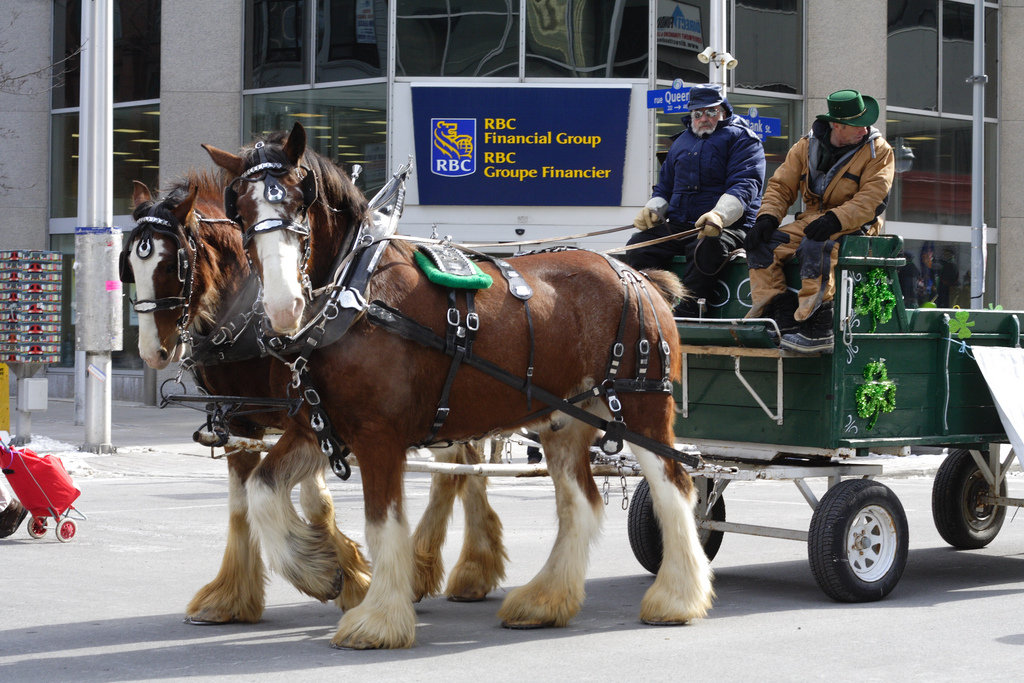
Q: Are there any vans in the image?
A: No, there are no vans.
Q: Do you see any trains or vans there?
A: No, there are no vans or trains.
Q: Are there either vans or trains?
A: No, there are no vans or trains.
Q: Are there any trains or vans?
A: No, there are no vans or trains.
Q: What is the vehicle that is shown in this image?
A: The vehicle is a wagon.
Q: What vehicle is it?
A: The vehicle is a wagon.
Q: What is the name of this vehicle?
A: This is a wagon.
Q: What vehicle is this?
A: This is a wagon.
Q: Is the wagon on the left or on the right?
A: The wagon is on the right of the image.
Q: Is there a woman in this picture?
A: No, there are no women.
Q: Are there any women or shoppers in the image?
A: No, there are no women or shoppers.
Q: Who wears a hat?
A: The man wears a hat.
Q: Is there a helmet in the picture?
A: No, there are no helmets.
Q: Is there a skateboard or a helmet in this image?
A: No, there are no helmets or skateboards.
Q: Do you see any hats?
A: Yes, there is a hat.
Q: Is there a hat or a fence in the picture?
A: Yes, there is a hat.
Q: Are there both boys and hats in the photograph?
A: No, there is a hat but no boys.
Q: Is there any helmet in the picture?
A: No, there are no helmets.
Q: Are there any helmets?
A: No, there are no helmets.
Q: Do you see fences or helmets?
A: No, there are no helmets or fences.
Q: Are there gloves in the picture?
A: Yes, there are gloves.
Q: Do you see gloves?
A: Yes, there are gloves.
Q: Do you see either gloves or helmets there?
A: Yes, there are gloves.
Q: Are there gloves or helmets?
A: Yes, there are gloves.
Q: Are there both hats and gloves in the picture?
A: Yes, there are both gloves and a hat.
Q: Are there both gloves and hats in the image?
A: Yes, there are both gloves and a hat.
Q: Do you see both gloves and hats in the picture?
A: Yes, there are both gloves and a hat.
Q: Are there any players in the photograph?
A: No, there are no players.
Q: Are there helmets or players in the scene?
A: No, there are no players or helmets.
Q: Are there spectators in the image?
A: No, there are no spectators.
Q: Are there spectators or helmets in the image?
A: No, there are no spectators or helmets.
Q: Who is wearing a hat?
A: The man is wearing a hat.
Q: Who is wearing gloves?
A: The man is wearing gloves.